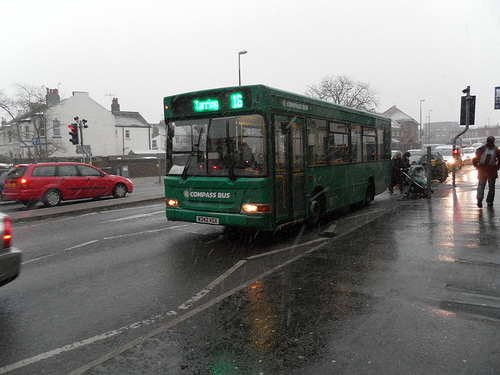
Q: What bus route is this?
A: 16.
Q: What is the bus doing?
A: Driving in the rain.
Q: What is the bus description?
A: Green bus.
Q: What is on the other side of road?
A: White buildings.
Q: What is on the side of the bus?
A: A door.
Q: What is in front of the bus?
A: Headlights.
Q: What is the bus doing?
A: Driving down road.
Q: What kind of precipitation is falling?
A: Snow.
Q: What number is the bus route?
A: 16.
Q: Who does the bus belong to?
A: Compass Bus.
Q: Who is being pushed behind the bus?
A: A baby.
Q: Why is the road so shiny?
A: It is wet.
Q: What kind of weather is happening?
A: Snow.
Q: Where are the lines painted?
A: On the road.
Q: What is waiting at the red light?
A: Red station wagon.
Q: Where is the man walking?
A: On the sidewalk.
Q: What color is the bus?
A: Green.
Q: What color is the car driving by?
A: Red.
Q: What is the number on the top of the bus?
A: 16.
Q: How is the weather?
A: Rainy.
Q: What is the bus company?
A: Compass Bus.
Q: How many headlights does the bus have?
A: Two.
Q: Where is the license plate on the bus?
A: Bottom front.